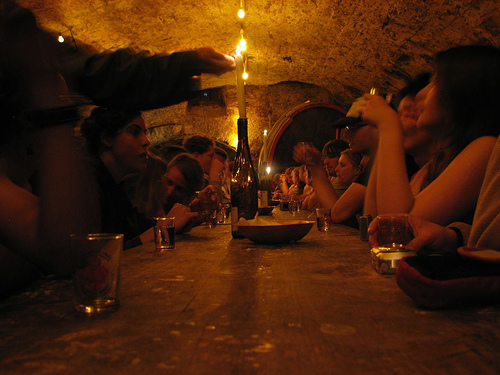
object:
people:
[66, 107, 230, 240]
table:
[4, 214, 496, 374]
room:
[0, 0, 500, 375]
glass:
[149, 214, 177, 254]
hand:
[163, 202, 209, 229]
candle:
[227, 51, 257, 124]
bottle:
[225, 117, 257, 239]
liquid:
[155, 227, 174, 245]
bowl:
[233, 217, 317, 246]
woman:
[355, 36, 498, 240]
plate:
[364, 247, 416, 273]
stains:
[139, 263, 190, 297]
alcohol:
[188, 73, 231, 114]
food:
[179, 196, 212, 228]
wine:
[227, 183, 257, 240]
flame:
[233, 44, 244, 56]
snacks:
[238, 205, 305, 226]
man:
[66, 102, 159, 245]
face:
[409, 75, 444, 132]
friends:
[181, 142, 319, 213]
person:
[184, 133, 224, 184]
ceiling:
[30, 0, 500, 49]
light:
[227, 5, 253, 25]